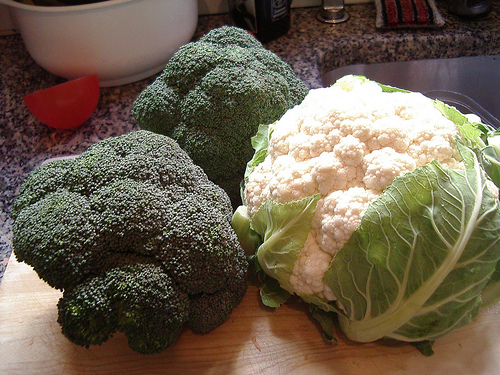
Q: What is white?
A: Cauliflower.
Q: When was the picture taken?
A: Daytime.